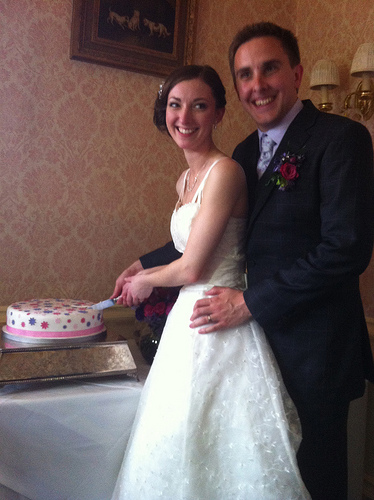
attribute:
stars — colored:
[23, 307, 53, 330]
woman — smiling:
[113, 62, 309, 495]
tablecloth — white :
[0, 368, 141, 496]